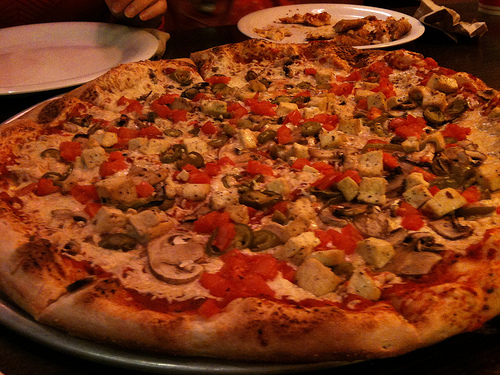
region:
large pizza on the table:
[9, 3, 463, 372]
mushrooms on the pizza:
[132, 225, 227, 298]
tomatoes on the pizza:
[189, 236, 279, 321]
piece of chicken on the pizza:
[253, 251, 332, 332]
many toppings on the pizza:
[91, 93, 416, 273]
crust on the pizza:
[110, 278, 396, 350]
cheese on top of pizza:
[99, 279, 195, 306]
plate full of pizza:
[209, 6, 426, 80]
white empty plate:
[0, 26, 160, 91]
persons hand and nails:
[111, 0, 168, 37]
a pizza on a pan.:
[0, 44, 498, 369]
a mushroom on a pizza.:
[143, 214, 211, 294]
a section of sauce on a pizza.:
[197, 229, 294, 311]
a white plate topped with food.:
[237, 0, 432, 53]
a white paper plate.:
[0, 14, 168, 99]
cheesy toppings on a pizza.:
[37, 74, 491, 276]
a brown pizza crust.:
[199, 274, 387, 356]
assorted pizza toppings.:
[347, 157, 392, 204]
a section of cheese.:
[184, 129, 212, 171]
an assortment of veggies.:
[292, 141, 411, 227]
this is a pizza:
[118, 92, 374, 199]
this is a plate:
[30, 37, 65, 65]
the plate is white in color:
[25, 36, 63, 56]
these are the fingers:
[121, 3, 151, 15]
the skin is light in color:
[148, 7, 159, 20]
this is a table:
[440, 37, 475, 54]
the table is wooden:
[468, 40, 498, 60]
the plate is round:
[6, 24, 101, 83]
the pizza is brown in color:
[166, 100, 373, 342]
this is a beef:
[343, 22, 376, 36]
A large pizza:
[0, 42, 490, 349]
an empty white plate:
[0, 23, 165, 89]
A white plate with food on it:
[246, 7, 411, 47]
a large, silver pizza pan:
[4, 48, 483, 372]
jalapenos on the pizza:
[200, 206, 298, 275]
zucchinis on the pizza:
[339, 149, 394, 231]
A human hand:
[97, 0, 189, 35]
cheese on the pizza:
[0, 76, 498, 283]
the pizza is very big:
[106, 84, 491, 324]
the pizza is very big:
[132, 90, 332, 311]